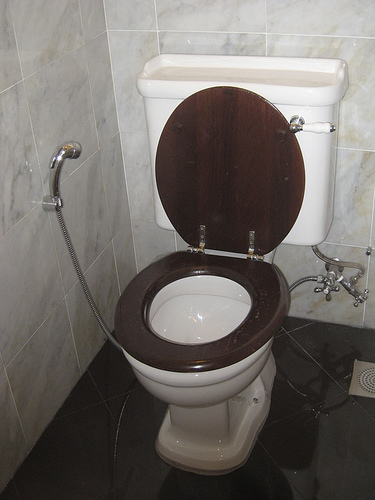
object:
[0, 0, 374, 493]
wall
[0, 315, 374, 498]
floor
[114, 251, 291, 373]
seat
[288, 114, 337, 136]
handle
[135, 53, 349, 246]
tank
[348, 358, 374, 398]
drain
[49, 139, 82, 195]
spray nozzle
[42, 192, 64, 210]
holder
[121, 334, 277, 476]
toilet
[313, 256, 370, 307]
knobs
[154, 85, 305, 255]
lid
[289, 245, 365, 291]
pipe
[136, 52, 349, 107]
lid